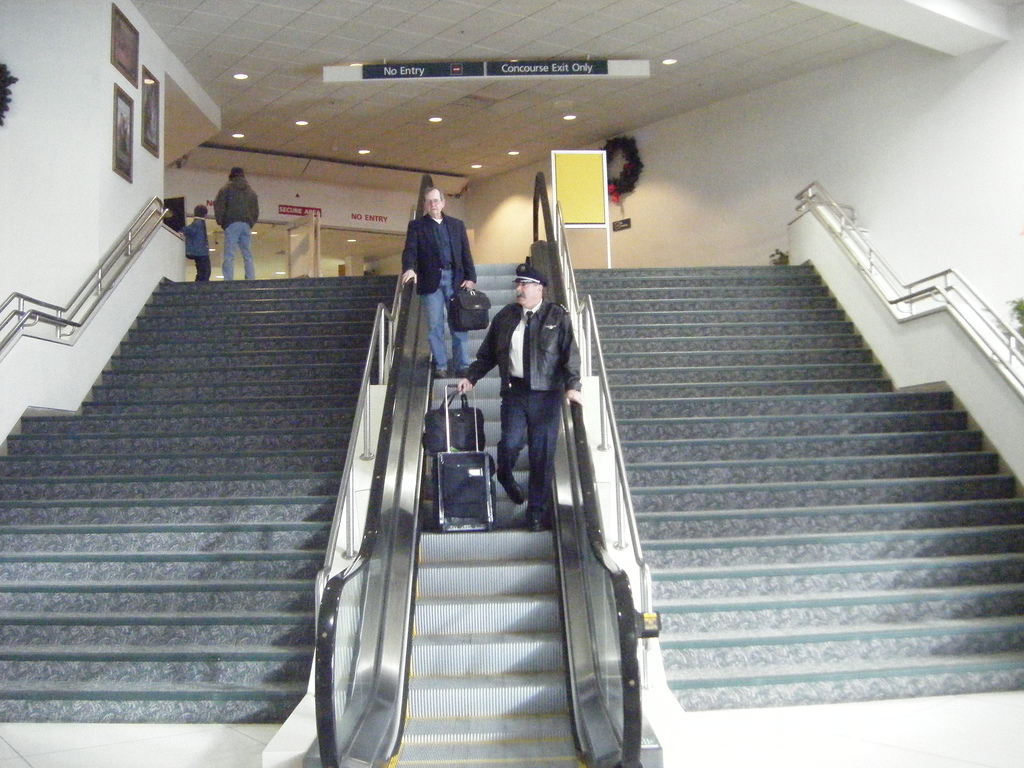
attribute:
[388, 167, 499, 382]
person — standing up